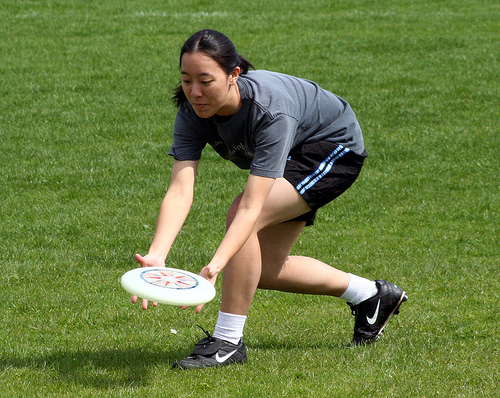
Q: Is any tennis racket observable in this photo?
A: No, there are no rackets.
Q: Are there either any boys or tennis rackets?
A: No, there are no tennis rackets or boys.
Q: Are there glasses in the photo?
A: No, there are no glasses.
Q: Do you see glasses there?
A: No, there are no glasses.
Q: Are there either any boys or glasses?
A: No, there are no glasses or boys.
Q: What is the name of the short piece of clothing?
A: The clothing item is a shirt.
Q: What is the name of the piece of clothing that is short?
A: The clothing item is a shirt.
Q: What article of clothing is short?
A: The clothing item is a shirt.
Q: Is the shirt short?
A: Yes, the shirt is short.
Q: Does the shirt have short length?
A: Yes, the shirt is short.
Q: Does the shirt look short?
A: Yes, the shirt is short.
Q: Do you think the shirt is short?
A: Yes, the shirt is short.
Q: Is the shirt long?
A: No, the shirt is short.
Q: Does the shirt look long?
A: No, the shirt is short.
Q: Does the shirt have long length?
A: No, the shirt is short.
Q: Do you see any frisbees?
A: Yes, there is a frisbee.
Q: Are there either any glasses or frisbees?
A: Yes, there is a frisbee.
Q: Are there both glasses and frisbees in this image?
A: No, there is a frisbee but no glasses.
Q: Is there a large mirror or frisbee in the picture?
A: Yes, there is a large frisbee.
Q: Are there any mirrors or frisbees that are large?
A: Yes, the frisbee is large.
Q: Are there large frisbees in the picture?
A: Yes, there is a large frisbee.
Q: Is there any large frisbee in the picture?
A: Yes, there is a large frisbee.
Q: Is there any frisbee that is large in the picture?
A: Yes, there is a large frisbee.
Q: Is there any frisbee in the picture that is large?
A: Yes, there is a frisbee that is large.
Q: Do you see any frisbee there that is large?
A: Yes, there is a frisbee that is large.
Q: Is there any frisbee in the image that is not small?
A: Yes, there is a large frisbee.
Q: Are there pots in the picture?
A: No, there are no pots.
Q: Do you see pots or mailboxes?
A: No, there are no pots or mailboxes.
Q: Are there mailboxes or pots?
A: No, there are no pots or mailboxes.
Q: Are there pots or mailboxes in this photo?
A: No, there are no pots or mailboxes.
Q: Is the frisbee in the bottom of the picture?
A: Yes, the frisbee is in the bottom of the image.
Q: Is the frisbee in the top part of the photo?
A: No, the frisbee is in the bottom of the image.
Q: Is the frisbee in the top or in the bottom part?
A: The frisbee is in the bottom of the image.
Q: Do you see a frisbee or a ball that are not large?
A: No, there is a frisbee but it is large.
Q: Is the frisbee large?
A: Yes, the frisbee is large.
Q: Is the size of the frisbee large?
A: Yes, the frisbee is large.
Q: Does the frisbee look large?
A: Yes, the frisbee is large.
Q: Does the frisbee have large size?
A: Yes, the frisbee is large.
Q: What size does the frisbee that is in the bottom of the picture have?
A: The frisbee has large size.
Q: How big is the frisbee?
A: The frisbee is large.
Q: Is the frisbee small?
A: No, the frisbee is large.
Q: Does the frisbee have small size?
A: No, the frisbee is large.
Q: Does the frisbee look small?
A: No, the frisbee is large.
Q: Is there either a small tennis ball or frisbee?
A: No, there is a frisbee but it is large.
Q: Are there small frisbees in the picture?
A: No, there is a frisbee but it is large.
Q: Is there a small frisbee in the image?
A: No, there is a frisbee but it is large.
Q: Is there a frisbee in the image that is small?
A: No, there is a frisbee but it is large.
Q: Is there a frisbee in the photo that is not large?
A: No, there is a frisbee but it is large.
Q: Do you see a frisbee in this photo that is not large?
A: No, there is a frisbee but it is large.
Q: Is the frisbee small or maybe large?
A: The frisbee is large.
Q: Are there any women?
A: Yes, there is a woman.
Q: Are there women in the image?
A: Yes, there is a woman.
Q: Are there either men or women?
A: Yes, there is a woman.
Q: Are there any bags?
A: No, there are no bags.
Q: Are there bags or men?
A: No, there are no bags or men.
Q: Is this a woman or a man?
A: This is a woman.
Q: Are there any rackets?
A: No, there are no rackets.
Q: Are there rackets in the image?
A: No, there are no rackets.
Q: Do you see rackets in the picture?
A: No, there are no rackets.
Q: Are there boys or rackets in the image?
A: No, there are no rackets or boys.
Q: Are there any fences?
A: No, there are no fences.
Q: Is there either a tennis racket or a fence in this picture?
A: No, there are no fences or rackets.